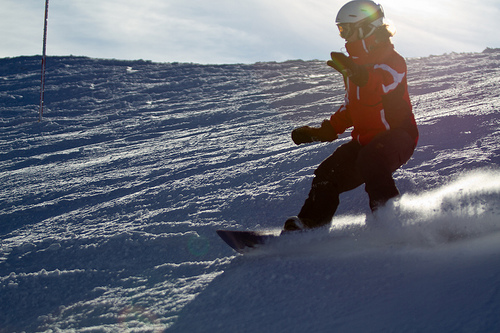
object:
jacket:
[323, 36, 415, 144]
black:
[330, 154, 376, 183]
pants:
[297, 140, 415, 229]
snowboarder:
[284, 0, 420, 233]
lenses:
[337, 25, 347, 38]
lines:
[38, 121, 221, 236]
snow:
[0, 45, 499, 332]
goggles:
[336, 22, 358, 38]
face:
[336, 24, 357, 43]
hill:
[0, 55, 173, 127]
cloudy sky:
[56, 2, 341, 61]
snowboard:
[214, 229, 272, 259]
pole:
[38, 0, 50, 118]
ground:
[0, 52, 498, 331]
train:
[335, 1, 389, 31]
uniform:
[289, 28, 421, 231]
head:
[334, 0, 389, 49]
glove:
[291, 119, 339, 145]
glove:
[326, 52, 366, 85]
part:
[231, 230, 261, 236]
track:
[66, 130, 196, 204]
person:
[280, 0, 424, 234]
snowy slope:
[10, 50, 499, 313]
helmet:
[335, 0, 387, 39]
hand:
[326, 51, 361, 79]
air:
[264, 173, 498, 273]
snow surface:
[2, 70, 238, 254]